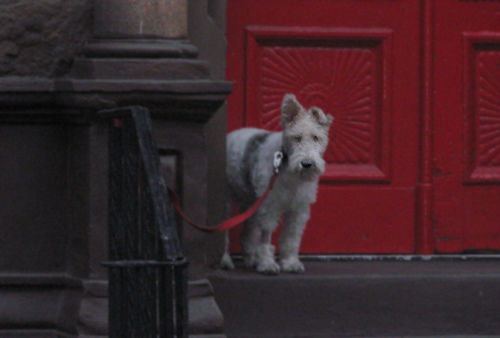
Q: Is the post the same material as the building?
A: Yes, both the post and the building are made of cement.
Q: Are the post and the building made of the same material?
A: Yes, both the post and the building are made of cement.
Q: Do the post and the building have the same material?
A: Yes, both the post and the building are made of cement.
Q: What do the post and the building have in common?
A: The material, both the post and the building are concrete.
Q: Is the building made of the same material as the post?
A: Yes, both the building and the post are made of cement.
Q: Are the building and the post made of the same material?
A: Yes, both the building and the post are made of cement.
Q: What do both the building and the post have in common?
A: The material, both the building and the post are concrete.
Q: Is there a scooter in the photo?
A: No, there are no scooters.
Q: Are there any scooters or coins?
A: No, there are no scooters or coins.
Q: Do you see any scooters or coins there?
A: No, there are no scooters or coins.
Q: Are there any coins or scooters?
A: No, there are no scooters or coins.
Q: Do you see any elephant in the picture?
A: No, there are no elephants.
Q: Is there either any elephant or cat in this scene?
A: No, there are no elephants or cats.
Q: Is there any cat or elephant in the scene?
A: No, there are no elephants or cats.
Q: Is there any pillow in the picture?
A: No, there are no pillows.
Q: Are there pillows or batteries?
A: No, there are no pillows or batteries.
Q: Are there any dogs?
A: Yes, there is a dog.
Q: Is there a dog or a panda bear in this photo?
A: Yes, there is a dog.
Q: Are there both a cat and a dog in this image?
A: No, there is a dog but no cats.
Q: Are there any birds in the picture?
A: No, there are no birds.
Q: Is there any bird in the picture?
A: No, there are no birds.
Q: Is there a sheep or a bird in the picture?
A: No, there are no birds or sheep.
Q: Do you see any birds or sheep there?
A: No, there are no birds or sheep.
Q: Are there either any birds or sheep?
A: No, there are no birds or sheep.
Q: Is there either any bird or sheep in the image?
A: No, there are no birds or sheep.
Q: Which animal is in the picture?
A: The animal is a dog.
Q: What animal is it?
A: The animal is a dog.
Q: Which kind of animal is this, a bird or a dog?
A: This is a dog.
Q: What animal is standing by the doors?
A: The animal is a dog.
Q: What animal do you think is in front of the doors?
A: The dog is in front of the doors.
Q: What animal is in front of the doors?
A: The animal is a dog.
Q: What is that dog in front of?
A: The dog is in front of the doors.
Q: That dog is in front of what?
A: The dog is in front of the doors.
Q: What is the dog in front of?
A: The dog is in front of the doors.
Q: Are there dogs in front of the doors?
A: Yes, there is a dog in front of the doors.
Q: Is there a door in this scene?
A: Yes, there are doors.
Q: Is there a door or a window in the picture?
A: Yes, there are doors.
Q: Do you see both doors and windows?
A: No, there are doors but no windows.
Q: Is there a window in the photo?
A: No, there are no windows.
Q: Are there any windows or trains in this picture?
A: No, there are no windows or trains.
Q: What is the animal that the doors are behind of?
A: The animal is a dog.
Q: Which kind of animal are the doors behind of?
A: The doors are behind the dog.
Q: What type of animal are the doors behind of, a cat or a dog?
A: The doors are behind a dog.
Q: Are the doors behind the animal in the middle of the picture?
A: Yes, the doors are behind the dog.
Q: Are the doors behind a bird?
A: No, the doors are behind the dog.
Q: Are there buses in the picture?
A: No, there are no buses.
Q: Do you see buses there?
A: No, there are no buses.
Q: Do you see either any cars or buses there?
A: No, there are no buses or cars.